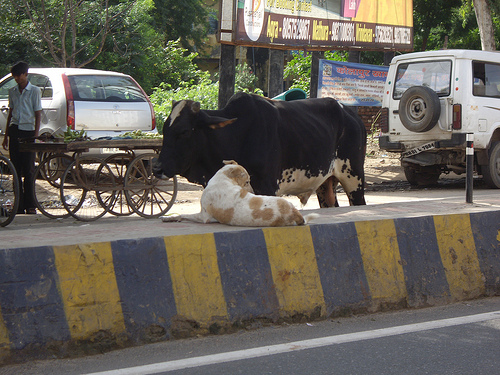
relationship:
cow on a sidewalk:
[143, 85, 375, 212] [2, 178, 498, 365]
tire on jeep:
[398, 85, 441, 132] [378, 45, 498, 190]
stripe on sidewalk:
[51, 238, 131, 351] [1, 188, 498, 248]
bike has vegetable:
[19, 139, 177, 221] [56, 126, 90, 144]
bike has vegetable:
[19, 139, 177, 221] [114, 127, 159, 139]